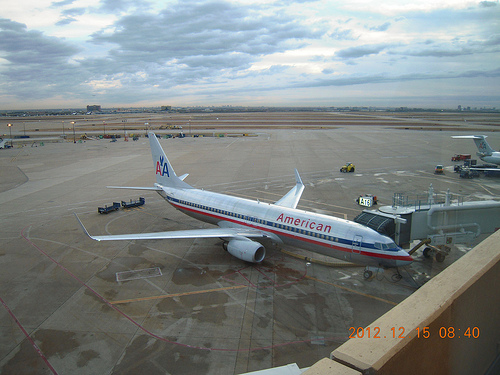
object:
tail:
[451, 135, 495, 156]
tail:
[107, 132, 195, 191]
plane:
[450, 134, 499, 170]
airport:
[0, 112, 500, 375]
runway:
[0, 129, 500, 375]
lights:
[62, 120, 77, 143]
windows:
[179, 199, 339, 241]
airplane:
[74, 132, 414, 278]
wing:
[274, 168, 306, 209]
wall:
[303, 357, 362, 375]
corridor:
[354, 200, 499, 245]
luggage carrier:
[97, 196, 145, 214]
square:
[116, 266, 163, 282]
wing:
[73, 211, 277, 241]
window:
[374, 241, 399, 249]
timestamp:
[349, 326, 480, 339]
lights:
[7, 122, 25, 147]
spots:
[156, 291, 229, 324]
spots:
[171, 266, 239, 287]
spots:
[95, 257, 165, 284]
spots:
[127, 243, 151, 256]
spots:
[112, 333, 211, 374]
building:
[297, 229, 500, 375]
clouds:
[0, 0, 497, 109]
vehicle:
[340, 162, 355, 173]